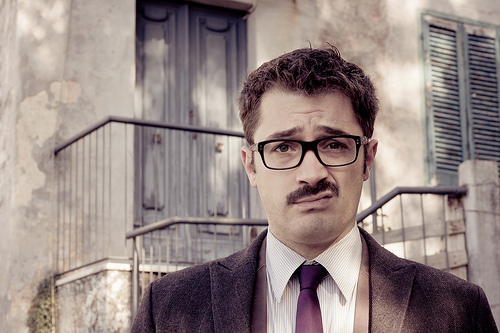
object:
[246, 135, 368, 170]
spectacle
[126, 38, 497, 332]
man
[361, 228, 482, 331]
shoulder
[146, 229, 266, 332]
shoulder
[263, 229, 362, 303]
collar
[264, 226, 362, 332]
shirt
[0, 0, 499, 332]
building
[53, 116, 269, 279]
railing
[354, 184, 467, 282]
railing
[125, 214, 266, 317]
railing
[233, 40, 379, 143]
hair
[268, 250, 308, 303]
point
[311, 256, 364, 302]
point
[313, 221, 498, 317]
suit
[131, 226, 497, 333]
coat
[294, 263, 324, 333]
tie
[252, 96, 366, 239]
face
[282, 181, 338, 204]
mustache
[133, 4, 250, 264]
door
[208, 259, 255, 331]
lapel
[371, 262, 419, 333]
lapel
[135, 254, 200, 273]
platform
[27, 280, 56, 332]
vegetation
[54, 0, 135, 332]
wall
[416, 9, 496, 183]
window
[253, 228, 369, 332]
jacket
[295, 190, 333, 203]
lip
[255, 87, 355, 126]
forehead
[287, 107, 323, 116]
crease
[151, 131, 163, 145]
handle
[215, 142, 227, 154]
handle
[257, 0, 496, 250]
wall